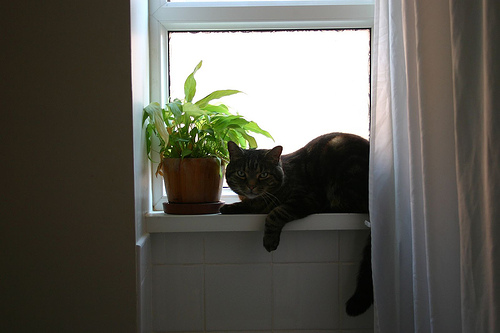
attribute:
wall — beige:
[1, 2, 133, 329]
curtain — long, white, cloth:
[372, 12, 499, 330]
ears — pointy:
[223, 137, 285, 160]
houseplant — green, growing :
[139, 70, 249, 223]